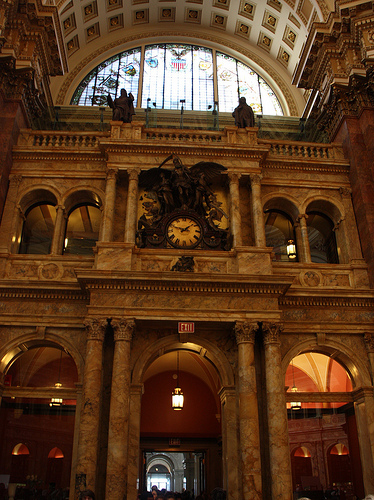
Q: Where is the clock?
A: On the building.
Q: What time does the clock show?
A: 1:50.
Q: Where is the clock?
A: On the wall.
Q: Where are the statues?
A: On the wall.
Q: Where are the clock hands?
A: On the clock.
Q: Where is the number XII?
A: On the sign.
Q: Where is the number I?
A: On the sign.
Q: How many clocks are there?
A: One.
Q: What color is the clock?
A: White.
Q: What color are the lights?
A: Yellow.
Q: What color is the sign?
A: Red and white.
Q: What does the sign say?
A: Exit.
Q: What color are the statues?
A: Brown.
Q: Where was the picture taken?
A: In a coliseum.